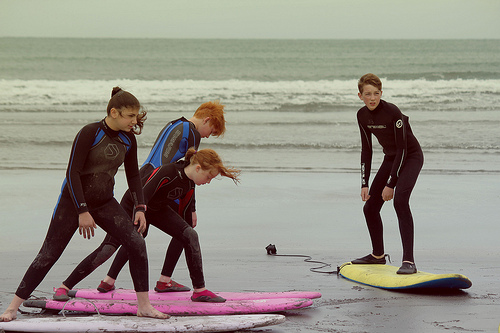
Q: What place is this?
A: It is a beach.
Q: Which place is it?
A: It is a beach.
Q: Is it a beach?
A: Yes, it is a beach.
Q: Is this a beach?
A: Yes, it is a beach.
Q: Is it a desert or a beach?
A: It is a beach.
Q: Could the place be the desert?
A: No, it is the beach.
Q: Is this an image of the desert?
A: No, the picture is showing the beach.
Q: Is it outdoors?
A: Yes, it is outdoors.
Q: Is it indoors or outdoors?
A: It is outdoors.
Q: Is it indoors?
A: No, it is outdoors.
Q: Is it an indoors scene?
A: No, it is outdoors.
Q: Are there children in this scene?
A: Yes, there are children.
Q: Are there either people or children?
A: Yes, there are children.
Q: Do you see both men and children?
A: No, there are children but no men.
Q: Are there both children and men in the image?
A: No, there are children but no men.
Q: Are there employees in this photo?
A: No, there are no employees.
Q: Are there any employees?
A: No, there are no employees.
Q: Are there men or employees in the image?
A: No, there are no employees or men.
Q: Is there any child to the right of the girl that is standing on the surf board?
A: Yes, there are children to the right of the girl.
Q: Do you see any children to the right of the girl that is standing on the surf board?
A: Yes, there are children to the right of the girl.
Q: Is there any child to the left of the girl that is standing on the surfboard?
A: No, the children are to the right of the girl.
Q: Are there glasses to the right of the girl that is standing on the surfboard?
A: No, there are children to the right of the girl.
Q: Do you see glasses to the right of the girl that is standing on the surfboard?
A: No, there are children to the right of the girl.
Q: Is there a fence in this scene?
A: No, there are no fences.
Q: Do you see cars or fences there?
A: No, there are no fences or cars.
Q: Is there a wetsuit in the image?
A: Yes, there is a wetsuit.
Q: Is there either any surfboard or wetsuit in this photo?
A: Yes, there is a wetsuit.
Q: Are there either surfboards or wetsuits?
A: Yes, there is a wetsuit.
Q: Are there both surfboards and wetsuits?
A: Yes, there are both a wetsuit and a surfboard.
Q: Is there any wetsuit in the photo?
A: Yes, there is a wetsuit.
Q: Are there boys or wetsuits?
A: Yes, there is a wetsuit.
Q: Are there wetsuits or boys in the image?
A: Yes, there is a wetsuit.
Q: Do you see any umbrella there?
A: No, there are no umbrellas.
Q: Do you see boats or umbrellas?
A: No, there are no umbrellas or boats.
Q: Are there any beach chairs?
A: No, there are no beach chairs.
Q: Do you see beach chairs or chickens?
A: No, there are no beach chairs or chickens.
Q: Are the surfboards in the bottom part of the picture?
A: Yes, the surfboards are in the bottom of the image.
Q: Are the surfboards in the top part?
A: No, the surfboards are in the bottom of the image.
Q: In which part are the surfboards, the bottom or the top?
A: The surfboards are in the bottom of the image.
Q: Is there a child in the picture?
A: Yes, there are children.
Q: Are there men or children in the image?
A: Yes, there are children.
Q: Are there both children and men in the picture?
A: No, there are children but no men.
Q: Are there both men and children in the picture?
A: No, there are children but no men.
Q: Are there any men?
A: No, there are no men.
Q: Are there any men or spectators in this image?
A: No, there are no men or spectators.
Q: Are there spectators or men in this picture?
A: No, there are no men or spectators.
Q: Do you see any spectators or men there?
A: No, there are no men or spectators.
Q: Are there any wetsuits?
A: Yes, there is a wetsuit.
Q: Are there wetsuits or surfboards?
A: Yes, there is a wetsuit.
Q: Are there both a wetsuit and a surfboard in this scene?
A: Yes, there are both a wetsuit and a surfboard.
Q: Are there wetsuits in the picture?
A: Yes, there is a wetsuit.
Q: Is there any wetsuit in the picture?
A: Yes, there is a wetsuit.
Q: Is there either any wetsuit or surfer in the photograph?
A: Yes, there is a wetsuit.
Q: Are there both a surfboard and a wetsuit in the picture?
A: Yes, there are both a wetsuit and a surfboard.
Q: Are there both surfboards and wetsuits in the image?
A: Yes, there are both a wetsuit and a surfboard.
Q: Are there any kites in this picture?
A: No, there are no kites.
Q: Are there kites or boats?
A: No, there are no kites or boats.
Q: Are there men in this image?
A: No, there are no men.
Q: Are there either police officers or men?
A: No, there are no men or police officers.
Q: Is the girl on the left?
A: Yes, the girl is on the left of the image.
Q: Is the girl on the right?
A: No, the girl is on the left of the image.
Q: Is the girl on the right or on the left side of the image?
A: The girl is on the left of the image.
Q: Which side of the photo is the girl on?
A: The girl is on the left of the image.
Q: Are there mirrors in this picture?
A: No, there are no mirrors.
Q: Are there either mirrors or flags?
A: No, there are no mirrors or flags.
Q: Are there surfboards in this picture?
A: Yes, there is a surfboard.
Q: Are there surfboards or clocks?
A: Yes, there is a surfboard.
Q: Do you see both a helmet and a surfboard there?
A: No, there is a surfboard but no helmets.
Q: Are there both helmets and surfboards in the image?
A: No, there is a surfboard but no helmets.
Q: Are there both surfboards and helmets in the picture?
A: No, there is a surfboard but no helmets.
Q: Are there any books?
A: No, there are no books.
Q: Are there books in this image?
A: No, there are no books.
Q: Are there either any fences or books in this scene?
A: No, there are no books or fences.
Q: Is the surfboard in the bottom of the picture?
A: Yes, the surfboard is in the bottom of the image.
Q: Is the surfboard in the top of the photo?
A: No, the surfboard is in the bottom of the image.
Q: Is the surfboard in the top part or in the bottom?
A: The surfboard is in the bottom of the image.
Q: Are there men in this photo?
A: No, there are no men.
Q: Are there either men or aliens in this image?
A: No, there are no men or aliens.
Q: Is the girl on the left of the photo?
A: Yes, the girl is on the left of the image.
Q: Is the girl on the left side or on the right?
A: The girl is on the left of the image.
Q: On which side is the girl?
A: The girl is on the left of the image.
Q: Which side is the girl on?
A: The girl is on the left of the image.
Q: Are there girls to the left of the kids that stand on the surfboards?
A: Yes, there is a girl to the left of the children.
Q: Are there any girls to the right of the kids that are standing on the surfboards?
A: No, the girl is to the left of the kids.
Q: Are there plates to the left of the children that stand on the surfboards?
A: No, there is a girl to the left of the children.